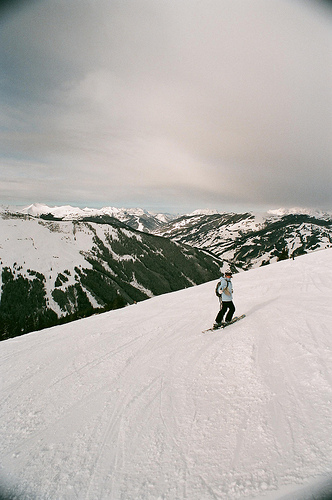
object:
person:
[213, 267, 235, 326]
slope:
[0, 246, 331, 497]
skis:
[202, 314, 246, 333]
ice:
[0, 245, 330, 498]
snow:
[0, 205, 332, 500]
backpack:
[216, 278, 229, 297]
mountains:
[0, 206, 330, 341]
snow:
[54, 203, 80, 213]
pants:
[215, 301, 235, 323]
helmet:
[225, 265, 233, 273]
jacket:
[218, 278, 234, 302]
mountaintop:
[0, 203, 331, 224]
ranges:
[0, 211, 332, 341]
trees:
[0, 279, 47, 334]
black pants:
[215, 300, 235, 323]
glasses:
[225, 273, 232, 278]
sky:
[0, 1, 330, 209]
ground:
[0, 218, 332, 500]